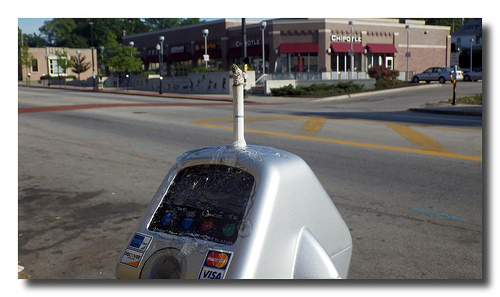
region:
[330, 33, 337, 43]
letter c on building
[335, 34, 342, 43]
letter h on building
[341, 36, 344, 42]
letter i on building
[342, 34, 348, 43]
letter p on building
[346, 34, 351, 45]
letter o on building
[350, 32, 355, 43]
letter t on building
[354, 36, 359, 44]
letter l on building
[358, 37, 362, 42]
letter e on building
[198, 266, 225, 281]
visa logo on machine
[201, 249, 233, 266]
mastercard logo on machine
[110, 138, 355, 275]
The top of a parking meter.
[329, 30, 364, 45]
A chipotle sign.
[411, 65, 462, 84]
A silver parked car.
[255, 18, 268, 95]
A light post.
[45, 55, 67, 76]
A white window.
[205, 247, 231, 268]
The mastercard logo.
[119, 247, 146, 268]
The discover card logo.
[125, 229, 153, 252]
The American express card logo.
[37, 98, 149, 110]
A red brick crosswalk.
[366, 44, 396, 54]
A burgundy awning.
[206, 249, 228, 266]
the red and yellow mastercard logo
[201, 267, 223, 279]
a blue and white visa logo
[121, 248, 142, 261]
a discover card logo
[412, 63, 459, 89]
a silver parked car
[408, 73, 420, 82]
a black rubber tire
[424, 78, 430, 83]
a black rubber tire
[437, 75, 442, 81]
a black rubber tire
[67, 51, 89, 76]
a small green tree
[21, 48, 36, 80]
a small green tree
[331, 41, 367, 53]
a red awning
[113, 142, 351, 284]
A silver box has a credit card sticker on it.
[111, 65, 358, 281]
A silver box has a white pipe on top.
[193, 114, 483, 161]
Yellow stripes are on the road.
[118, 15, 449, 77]
A building is red and light red.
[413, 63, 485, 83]
Two silver cars are next to each other.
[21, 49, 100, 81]
Sunlight is on a building.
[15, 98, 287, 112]
A red stripe is on a street.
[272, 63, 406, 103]
Bushes and plants are near a curb.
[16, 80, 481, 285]
A street has an intersection.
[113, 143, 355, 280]
A device is smeared with some white substance.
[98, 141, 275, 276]
the parking meter is broken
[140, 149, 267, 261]
the parking meter is broken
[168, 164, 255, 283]
the parking meter is broken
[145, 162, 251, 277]
the parking meter is broken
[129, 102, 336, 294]
the parking meter is silver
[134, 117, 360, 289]
the parking meter is silver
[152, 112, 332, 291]
the parking meter is silver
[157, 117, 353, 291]
the parking meter is silver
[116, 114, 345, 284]
the parking meter is silver